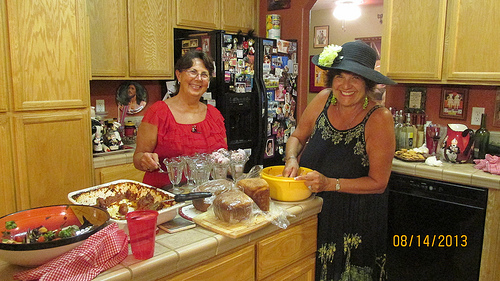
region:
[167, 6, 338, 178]
black double door fridge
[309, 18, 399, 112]
lady wearing black hat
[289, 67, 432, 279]
lady wearing black dress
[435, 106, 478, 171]
red jug on counter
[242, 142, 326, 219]
yellow dish on counter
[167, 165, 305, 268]
bread loaves on cutting board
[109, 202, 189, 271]
red cup on the counter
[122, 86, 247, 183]
lady wearing red top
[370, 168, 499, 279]
black dish washer in kitchen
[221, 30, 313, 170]
stickers on fridge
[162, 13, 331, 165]
black double door fridge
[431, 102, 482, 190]
red jug on counter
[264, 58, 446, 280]
lady wearing black dress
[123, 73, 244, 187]
lady wearing red top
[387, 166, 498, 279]
black dishwasher in kitchen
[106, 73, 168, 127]
Jesus picture on wall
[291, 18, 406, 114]
lady wearing a black hat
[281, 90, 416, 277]
lady wearing black dress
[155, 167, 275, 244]
bread loaves on cutting board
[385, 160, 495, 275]
black dishwasher in kitchen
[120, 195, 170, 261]
red cup on counter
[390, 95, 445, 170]
liquor bottles on counter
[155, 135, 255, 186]
desert cups on counter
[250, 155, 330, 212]
yellow dish on counter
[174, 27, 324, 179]
black double door fridge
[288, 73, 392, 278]
black and flowered dress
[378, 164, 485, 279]
black door on oven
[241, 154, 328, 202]
yellow bowl on table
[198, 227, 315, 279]
brown drawers on counter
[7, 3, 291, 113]
brown cabinets above fridge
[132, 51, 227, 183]
a woman standing in a kitchen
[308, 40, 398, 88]
woman wearing a black hat with a white flower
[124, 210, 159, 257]
a red plastic glass on a counter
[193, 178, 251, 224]
loaves of brad wrapped in a plastic bag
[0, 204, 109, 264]
a large bowl containing salad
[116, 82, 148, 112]
a round painting of Jesus on the wall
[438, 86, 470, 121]
a wooden framed painting on a red wall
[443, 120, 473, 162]
a red and black pitcher on a counter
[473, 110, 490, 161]
an empty bottle of wine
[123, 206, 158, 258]
A pink cup on the counter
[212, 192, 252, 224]
Bread on a cutting board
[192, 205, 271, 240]
A cutting board on a counter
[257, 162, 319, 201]
A yellow bowl on a counter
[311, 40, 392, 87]
A black hat on a woman's head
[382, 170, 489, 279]
A dishwasher in the kitchen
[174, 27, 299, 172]
A refrigerator in the kitchen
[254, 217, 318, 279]
A wood drawer in the kitchen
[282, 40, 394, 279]
A woman standing in the kitchen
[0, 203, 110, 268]
A large bowl on the counter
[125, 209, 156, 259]
pink plastic cup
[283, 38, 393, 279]
woman wearing a black hat and dress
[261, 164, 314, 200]
yellow plastic mixing bowl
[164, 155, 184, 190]
empty glass sundae dish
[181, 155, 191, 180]
empty glass sundae dish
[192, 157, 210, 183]
empty glass sundae dish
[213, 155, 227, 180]
empty glass sundae dish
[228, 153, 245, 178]
empty glass sundae dish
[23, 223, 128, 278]
red and white checkered hand towel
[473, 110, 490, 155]
dark green wine bottle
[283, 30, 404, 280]
woman mixing food in bowl